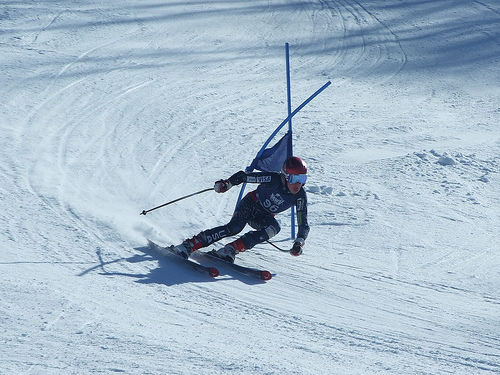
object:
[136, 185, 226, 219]
pole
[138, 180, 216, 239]
ski pole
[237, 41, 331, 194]
banner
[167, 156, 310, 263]
racer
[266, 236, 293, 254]
pole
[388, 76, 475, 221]
sport skiing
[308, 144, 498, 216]
snow`s clumps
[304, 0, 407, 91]
track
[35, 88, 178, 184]
tracks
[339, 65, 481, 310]
snow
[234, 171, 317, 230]
top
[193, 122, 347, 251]
marker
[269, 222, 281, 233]
knee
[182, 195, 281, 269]
ski pants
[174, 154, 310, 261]
man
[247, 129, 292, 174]
flag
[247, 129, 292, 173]
blue flag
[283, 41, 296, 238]
pole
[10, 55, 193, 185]
tracks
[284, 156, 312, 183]
helmet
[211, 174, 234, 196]
hand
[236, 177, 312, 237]
chest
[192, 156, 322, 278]
person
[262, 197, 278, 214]
96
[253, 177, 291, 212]
torso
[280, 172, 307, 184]
goggles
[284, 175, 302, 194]
face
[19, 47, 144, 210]
bmx bike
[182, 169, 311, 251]
outfit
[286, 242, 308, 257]
hand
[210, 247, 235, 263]
foot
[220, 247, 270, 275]
ski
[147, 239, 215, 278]
ski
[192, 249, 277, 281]
red skis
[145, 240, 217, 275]
red skis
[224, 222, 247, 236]
knee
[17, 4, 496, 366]
trail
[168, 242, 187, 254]
foot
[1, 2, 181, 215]
snow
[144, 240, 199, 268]
ski shoes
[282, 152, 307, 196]
head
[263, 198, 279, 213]
number 36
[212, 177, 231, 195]
right hand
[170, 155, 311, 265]
skier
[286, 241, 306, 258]
left hand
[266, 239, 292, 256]
ski pole